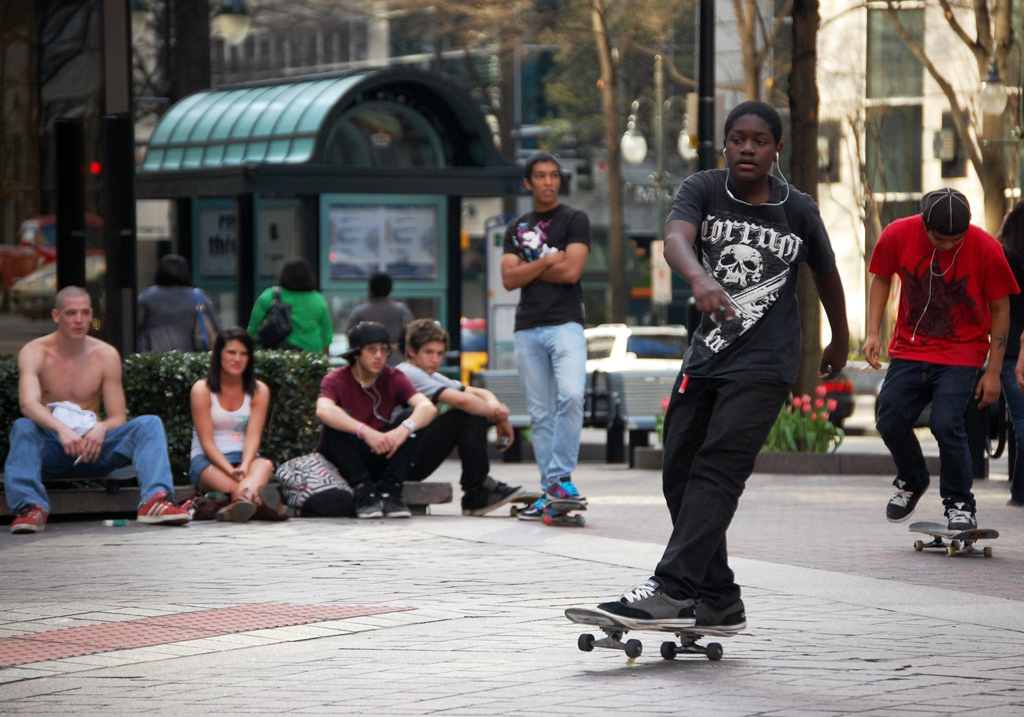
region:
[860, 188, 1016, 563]
A skateboarder wearing a red shirt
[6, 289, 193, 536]
A man sitting without a shirt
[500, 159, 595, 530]
A kid standing on a skateboard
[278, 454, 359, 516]
A bag laying on the ground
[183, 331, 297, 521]
A woman wearing a tank top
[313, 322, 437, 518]
A kid wearing headphones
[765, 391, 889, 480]
A planter with flowers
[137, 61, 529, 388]
A covered bus stop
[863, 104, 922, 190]
A window in a building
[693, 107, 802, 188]
boy has black hair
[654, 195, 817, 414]
black and white shirt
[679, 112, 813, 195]
boy has white earbuds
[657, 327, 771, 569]
boy has black pants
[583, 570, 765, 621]
black and white shoes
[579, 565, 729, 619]
black and white skateboard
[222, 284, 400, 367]
woman has green shirt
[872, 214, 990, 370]
red and black shirt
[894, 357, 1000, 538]
boy has blue jeans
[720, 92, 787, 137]
Person has short hair.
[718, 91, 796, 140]
Person has black hair.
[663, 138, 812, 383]
Person wearing black t-shirt.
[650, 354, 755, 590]
Person wearing black pants.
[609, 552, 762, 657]
Person wearing tennis shoes.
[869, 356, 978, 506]
Person wearing dark pants.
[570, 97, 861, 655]
boy is riding a skateboard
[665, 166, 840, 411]
boy is wearing a black and white shirt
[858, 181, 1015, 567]
boy riding a skateboard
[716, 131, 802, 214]
boy is wearing headphones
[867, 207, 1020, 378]
boys shirt is red and black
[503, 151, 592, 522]
boy has one foot on skateboard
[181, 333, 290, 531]
girl is wearing a white tank top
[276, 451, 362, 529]
bag on ground is black and white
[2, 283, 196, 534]
man is holding a cigarette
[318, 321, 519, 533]
boy is wearing a burgundy colored shirt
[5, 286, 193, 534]
a shirtless young man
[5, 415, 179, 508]
a pair of blue jeans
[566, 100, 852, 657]
a young man riding a skateboard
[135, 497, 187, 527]
a red and white athletic shoe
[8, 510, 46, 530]
a red and white athletic shoe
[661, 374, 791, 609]
a pair of black jeans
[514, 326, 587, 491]
a pair of blue jeans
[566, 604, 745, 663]
a white skateboard with black wheels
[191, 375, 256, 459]
a woman's white printed tank top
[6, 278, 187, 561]
The man with no shirt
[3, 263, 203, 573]
A man with no shirt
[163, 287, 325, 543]
The woman sitting down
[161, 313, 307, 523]
A woman sitting down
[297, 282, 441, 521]
The man in a maroon shirt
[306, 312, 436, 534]
A man in a maroon shirt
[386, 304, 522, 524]
A man in a blue shirt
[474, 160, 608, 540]
The man standing on the skateboard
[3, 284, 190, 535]
man is wearing red shoes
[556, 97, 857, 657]
boy is riding a skateboard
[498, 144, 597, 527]
man is standing with his arms crossed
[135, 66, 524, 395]
bus stop has green curved roof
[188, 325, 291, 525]
woman is wearing a white tank top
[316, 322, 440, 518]
boy is wearing a black baseball cap sideways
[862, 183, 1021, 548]
boy is wearing a red t-shirt with a black design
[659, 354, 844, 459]
plant has pink flowers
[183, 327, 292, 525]
woman has black straight hair